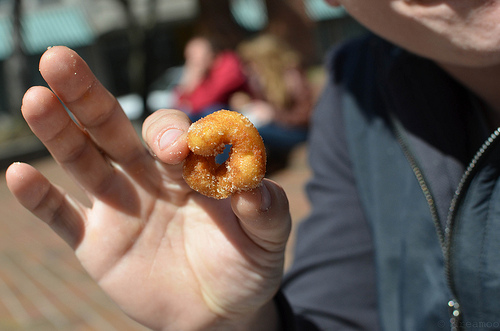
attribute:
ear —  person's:
[318, 2, 345, 24]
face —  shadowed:
[323, 4, 498, 84]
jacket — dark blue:
[275, 34, 499, 330]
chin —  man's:
[479, 22, 497, 46]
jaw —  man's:
[345, 17, 483, 61]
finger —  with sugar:
[27, 36, 88, 90]